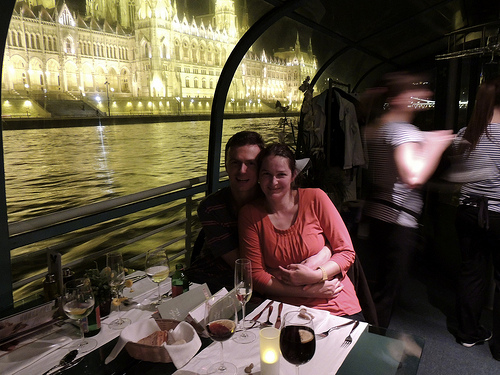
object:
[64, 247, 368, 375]
dinner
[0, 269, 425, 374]
table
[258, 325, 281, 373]
candle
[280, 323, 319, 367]
wine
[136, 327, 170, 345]
bread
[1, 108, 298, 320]
water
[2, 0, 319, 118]
building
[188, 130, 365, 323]
couple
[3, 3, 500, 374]
cruise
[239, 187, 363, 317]
shirt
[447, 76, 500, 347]
woman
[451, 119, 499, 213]
shirt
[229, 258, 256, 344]
glass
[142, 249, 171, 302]
glass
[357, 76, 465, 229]
lady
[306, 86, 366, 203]
jacket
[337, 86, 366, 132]
jacket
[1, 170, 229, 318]
railing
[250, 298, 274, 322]
knife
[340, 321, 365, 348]
fork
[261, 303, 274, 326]
spoon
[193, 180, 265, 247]
shirt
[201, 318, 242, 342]
wine